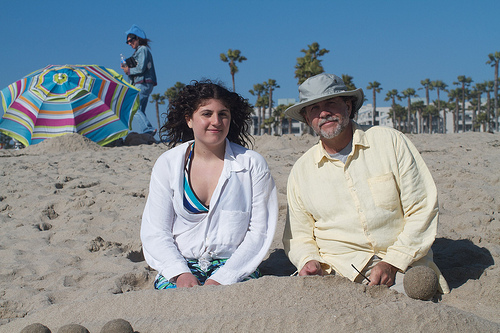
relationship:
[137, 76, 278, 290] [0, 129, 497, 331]
lady in sand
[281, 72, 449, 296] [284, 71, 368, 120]
man wearing hat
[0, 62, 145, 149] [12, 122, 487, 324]
rainbow umbrella on sand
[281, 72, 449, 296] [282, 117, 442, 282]
man wearing shirt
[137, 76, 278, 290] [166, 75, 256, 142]
lady has hair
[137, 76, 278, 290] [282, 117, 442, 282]
lady wearing shirt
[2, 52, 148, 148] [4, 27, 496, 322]
rainbow umbrella on beach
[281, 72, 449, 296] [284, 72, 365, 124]
man wearing grey hat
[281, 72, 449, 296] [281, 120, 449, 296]
man wearing shirt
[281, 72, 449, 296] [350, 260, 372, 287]
man holding glasses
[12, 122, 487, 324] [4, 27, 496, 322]
sand on beach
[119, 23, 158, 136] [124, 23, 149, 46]
lady wearing hat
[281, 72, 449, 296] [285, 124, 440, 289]
man wearing shirt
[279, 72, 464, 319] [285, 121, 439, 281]
man wearing shirt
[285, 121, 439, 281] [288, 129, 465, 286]
shirt on body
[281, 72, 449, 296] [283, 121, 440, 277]
man wearing yellow shirt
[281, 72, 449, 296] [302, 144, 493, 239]
man wearing yellow shirt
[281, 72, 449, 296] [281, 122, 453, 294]
man wearing yellow shirt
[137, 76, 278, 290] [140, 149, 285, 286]
lady wearing shirt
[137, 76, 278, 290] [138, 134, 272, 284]
lady wearing shirt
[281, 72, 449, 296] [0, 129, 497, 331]
man on sand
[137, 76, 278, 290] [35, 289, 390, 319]
lady on sand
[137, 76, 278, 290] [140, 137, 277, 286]
lady wearing shirt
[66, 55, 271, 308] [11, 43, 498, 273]
lady walking on beach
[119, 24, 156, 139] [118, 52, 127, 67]
lady holding bottle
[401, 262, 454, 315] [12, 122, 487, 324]
ball made of sand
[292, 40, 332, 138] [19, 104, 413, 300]
tree near beach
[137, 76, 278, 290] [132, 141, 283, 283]
lady wearing white shirt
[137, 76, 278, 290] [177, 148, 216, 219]
lady wearing top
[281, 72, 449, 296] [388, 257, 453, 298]
man wearing brown pants